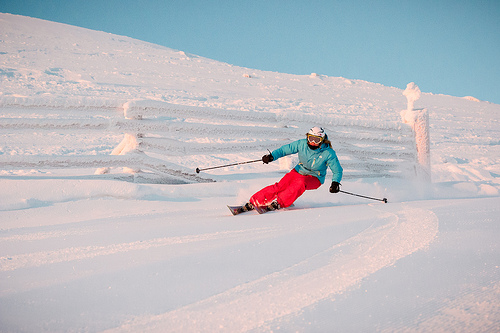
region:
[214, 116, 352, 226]
a skater on the snow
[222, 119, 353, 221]
skater wears red pants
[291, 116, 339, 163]
a white helmet on head of skater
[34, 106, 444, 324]
skier is on a snow track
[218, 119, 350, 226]
skier is bend to the right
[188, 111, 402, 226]
skier holds two snow poles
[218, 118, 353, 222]
skier wears black gloves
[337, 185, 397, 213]
a snow pole on right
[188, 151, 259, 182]
a snow pole on left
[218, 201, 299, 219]
skies are inclined on one side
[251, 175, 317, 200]
redskiers pants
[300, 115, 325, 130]
helmet on the skier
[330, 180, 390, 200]
left hand skie pole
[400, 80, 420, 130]
ornate ending to a fence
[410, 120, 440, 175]
pole covered in snow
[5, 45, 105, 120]
a portion of snow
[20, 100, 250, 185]
portion of fence covered in snow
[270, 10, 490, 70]
portion of blue sky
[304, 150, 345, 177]
blue jacket on skier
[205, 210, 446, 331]
tracks made by a vehicle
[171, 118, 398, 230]
skier turning to the left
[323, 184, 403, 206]
a ski pole in the left hand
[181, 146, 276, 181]
ski pole in the right hand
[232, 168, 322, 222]
pink snow pants on the skier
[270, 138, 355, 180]
blue jacket on a skier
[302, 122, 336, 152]
goggles on a skier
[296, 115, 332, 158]
a helmet on the skier's head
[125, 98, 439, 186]
fence behind the skier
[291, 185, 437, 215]
shadow of a skier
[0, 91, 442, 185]
a fence behind the person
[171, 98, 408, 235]
a person skiing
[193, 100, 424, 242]
a person in red snow pants skiing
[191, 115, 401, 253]
a person wearing blue and red snowsuit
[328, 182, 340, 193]
a glove of the person skiing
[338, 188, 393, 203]
a ski pole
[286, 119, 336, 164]
a person wearing goggle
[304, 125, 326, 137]
a helmet of the person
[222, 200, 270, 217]
a pair of skis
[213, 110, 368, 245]
a person wearing helmet and goggle skiing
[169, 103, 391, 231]
a skier going down the slope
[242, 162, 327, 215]
bright pink ski pants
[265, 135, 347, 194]
aqua blue winter coat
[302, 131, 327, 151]
orange and white safety goggles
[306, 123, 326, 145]
blue and white safety helmet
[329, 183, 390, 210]
ski pole in left hand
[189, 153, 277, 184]
ski pole in right hand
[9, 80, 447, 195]
snow covered white fence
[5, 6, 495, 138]
snow covered hill side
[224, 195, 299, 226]
pair of snow skis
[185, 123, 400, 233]
downhill skier leaning left